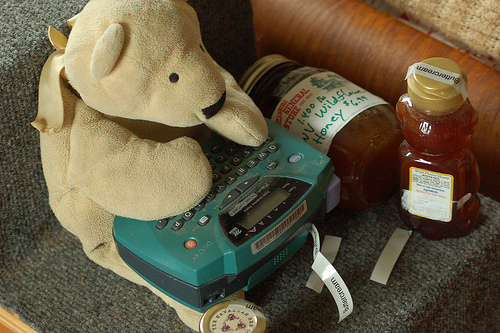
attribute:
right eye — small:
[157, 61, 186, 93]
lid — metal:
[248, 52, 276, 94]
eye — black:
[159, 55, 206, 112]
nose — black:
[204, 98, 234, 111]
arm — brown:
[83, 131, 248, 195]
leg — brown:
[90, 237, 250, 319]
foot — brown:
[169, 283, 305, 322]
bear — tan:
[44, 28, 253, 212]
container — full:
[393, 58, 487, 302]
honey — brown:
[377, 52, 498, 259]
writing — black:
[300, 270, 378, 314]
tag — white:
[352, 207, 412, 295]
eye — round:
[162, 68, 193, 98]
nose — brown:
[191, 99, 236, 119]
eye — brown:
[194, 38, 213, 68]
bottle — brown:
[400, 54, 488, 214]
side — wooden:
[252, 1, 483, 200]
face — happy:
[118, 6, 227, 128]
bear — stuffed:
[28, 0, 323, 329]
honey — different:
[281, 30, 499, 213]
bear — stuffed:
[35, 19, 267, 264]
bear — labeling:
[73, 21, 292, 283]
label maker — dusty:
[149, 130, 329, 305]